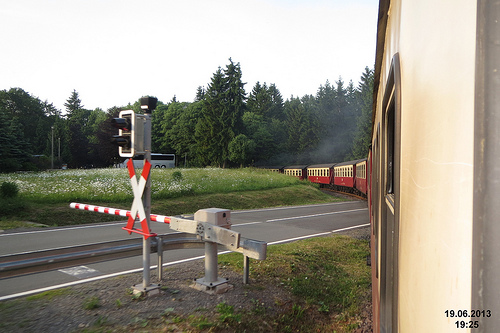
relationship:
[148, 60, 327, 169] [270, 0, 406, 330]
green trees behind train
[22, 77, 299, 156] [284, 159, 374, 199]
trees behind train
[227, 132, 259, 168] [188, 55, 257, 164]
trees have leaves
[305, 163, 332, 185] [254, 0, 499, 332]
car of train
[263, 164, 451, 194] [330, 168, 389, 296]
train traveling on tracks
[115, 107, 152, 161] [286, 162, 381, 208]
signal for train cars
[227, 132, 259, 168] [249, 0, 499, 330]
trees behind train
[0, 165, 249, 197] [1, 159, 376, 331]
white flowers are on ground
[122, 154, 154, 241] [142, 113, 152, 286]
x on post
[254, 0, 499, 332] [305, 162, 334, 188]
train on cargo car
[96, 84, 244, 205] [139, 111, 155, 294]
light on post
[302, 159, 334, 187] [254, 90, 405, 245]
car on train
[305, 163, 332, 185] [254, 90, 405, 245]
car on train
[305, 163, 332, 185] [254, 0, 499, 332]
car on train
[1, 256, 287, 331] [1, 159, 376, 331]
dirt on ground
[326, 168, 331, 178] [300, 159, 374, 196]
window on train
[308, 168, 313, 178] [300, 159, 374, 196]
window on train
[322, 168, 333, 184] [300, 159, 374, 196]
window on train